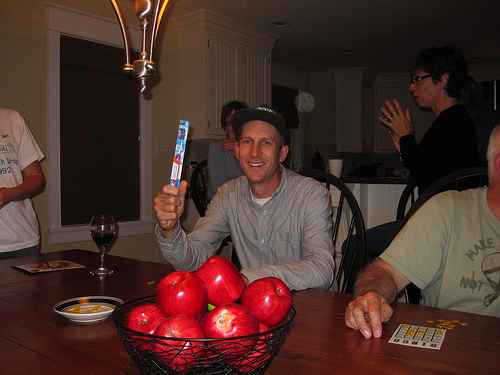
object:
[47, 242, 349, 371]
table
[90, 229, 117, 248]
wine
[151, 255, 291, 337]
apples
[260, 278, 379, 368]
table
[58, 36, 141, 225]
window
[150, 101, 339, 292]
man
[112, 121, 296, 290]
bowl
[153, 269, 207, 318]
apple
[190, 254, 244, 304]
apple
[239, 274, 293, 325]
apple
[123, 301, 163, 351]
apple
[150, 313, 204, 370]
apple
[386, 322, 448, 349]
bingo card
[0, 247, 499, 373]
table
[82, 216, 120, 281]
glass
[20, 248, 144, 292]
table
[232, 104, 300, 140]
hat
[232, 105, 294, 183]
man's head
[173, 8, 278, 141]
cabinet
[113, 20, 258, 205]
wall